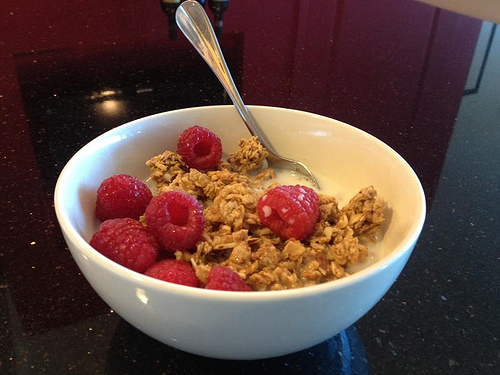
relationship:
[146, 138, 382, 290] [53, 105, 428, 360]
granola inside bowl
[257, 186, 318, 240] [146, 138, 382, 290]
raspberry near granola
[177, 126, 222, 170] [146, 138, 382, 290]
raspberry near granola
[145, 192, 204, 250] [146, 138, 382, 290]
raspberry near granola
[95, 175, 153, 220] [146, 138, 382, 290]
raspberry near granola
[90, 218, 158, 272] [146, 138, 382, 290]
raspberry near granola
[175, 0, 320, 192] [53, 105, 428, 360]
spoon in bowl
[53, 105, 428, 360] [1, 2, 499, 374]
bowl on top of counter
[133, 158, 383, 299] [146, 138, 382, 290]
milk under granola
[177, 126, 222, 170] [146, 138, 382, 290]
raspberry on granola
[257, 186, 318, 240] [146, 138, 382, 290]
raspberry on granola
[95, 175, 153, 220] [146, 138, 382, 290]
raspberry on granola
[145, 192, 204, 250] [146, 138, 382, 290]
raspberry on granola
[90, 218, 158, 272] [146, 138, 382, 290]
raspberry on granola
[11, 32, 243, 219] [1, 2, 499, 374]
reflection on counter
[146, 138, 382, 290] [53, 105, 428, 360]
granola in bowl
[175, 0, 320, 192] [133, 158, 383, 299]
spoon in milk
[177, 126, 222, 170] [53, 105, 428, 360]
raspberry in bowl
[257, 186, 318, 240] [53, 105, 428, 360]
raspberry in bowl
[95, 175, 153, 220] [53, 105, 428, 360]
raspberry in bowl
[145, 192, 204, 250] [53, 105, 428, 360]
raspberry in bowl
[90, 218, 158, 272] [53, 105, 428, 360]
raspberry in bowl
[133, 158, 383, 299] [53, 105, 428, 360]
milk in bowl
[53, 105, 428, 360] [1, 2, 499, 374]
bowl on counter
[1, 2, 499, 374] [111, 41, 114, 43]
counter has specks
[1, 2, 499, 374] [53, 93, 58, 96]
counter has specks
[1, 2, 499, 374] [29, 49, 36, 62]
counter has specks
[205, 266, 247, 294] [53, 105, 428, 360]
raspberry in bowl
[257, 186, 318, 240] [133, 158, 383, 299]
raspberry in milk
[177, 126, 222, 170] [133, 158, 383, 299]
raspberry in milk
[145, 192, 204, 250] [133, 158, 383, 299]
raspberry in milk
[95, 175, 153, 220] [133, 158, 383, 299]
raspberry in milk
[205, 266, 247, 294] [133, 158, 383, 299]
raspberry in milk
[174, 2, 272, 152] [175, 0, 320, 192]
handle on spoon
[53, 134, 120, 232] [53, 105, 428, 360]
reflection on bowl